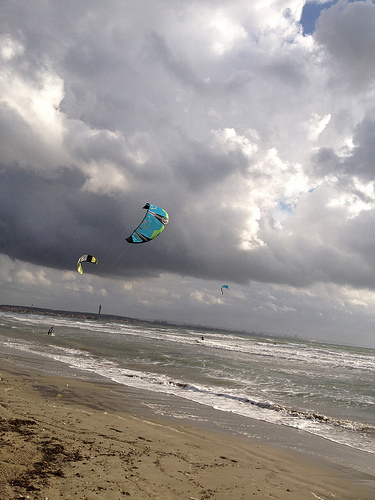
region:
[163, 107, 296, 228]
sun peeking through clouds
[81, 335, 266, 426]
small waves in ocean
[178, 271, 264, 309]
kite in the sky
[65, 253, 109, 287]
yellow black and white kite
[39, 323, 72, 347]
person in the water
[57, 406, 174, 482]
tracks in the sand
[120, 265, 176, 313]
clouds in the sky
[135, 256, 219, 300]
some grey clouds in the sky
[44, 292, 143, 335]
land in the background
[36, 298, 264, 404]
people in the ocean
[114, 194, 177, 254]
a C-kite in the sky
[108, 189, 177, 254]
kite is color blue, green and black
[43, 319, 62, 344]
a person in the water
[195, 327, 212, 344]
person wearing black cloths is in the water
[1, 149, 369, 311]
three kites on a cloudy sky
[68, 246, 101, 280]
a gray, yellow and black kite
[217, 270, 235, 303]
a blue kite over the ocean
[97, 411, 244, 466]
footsteps on the sand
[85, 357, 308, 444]
water over the sand is foamy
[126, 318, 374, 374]
many waves formed in the ocean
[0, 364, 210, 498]
Sand on the beach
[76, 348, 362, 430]
Dark grey water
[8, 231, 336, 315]
Big dark clouds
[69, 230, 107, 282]
Yellow, white, and black kite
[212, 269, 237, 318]
A blue kite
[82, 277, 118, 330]
A light house in the back ground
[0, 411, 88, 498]
Little sticks setting on the beach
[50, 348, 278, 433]
Little white caps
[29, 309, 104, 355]
A person doing water sports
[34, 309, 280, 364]
A rough current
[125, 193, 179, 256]
Bright Blue Windsurfing Sail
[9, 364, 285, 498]
A stretch of Sandy Beach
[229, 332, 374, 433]
A Large body of open water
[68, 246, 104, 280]
A Yellow Wind Surfing Sail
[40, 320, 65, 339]
People standing knee high in the water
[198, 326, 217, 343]
Man out in the deep water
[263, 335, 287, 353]
Wind Surfer Far away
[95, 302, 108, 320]
Possible Lighthouse Structure in the distance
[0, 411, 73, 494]
Some Seaweed leftover from high tide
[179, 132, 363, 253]
A Cloudy grey sky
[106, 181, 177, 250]
a beautiful blue parachuate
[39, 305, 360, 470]
a beautiful view of sea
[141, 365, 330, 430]
a small part of water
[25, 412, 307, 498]
beautiful sand on beach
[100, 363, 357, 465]
water coming out to sand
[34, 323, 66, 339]
a person in water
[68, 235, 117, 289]
a beautiful white parachuate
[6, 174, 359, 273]
deep black clouds in sky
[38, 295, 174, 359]
two persons in water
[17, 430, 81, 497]
a small hole in sand